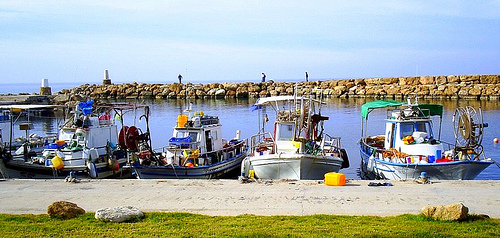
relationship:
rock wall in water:
[2, 75, 499, 103] [0, 83, 498, 180]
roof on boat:
[255, 96, 328, 107] [241, 95, 344, 179]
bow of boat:
[248, 155, 343, 179] [241, 95, 344, 179]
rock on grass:
[48, 201, 86, 220] [0, 214, 498, 237]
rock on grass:
[420, 203, 468, 222] [0, 214, 498, 237]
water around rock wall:
[0, 83, 498, 180] [2, 75, 499, 103]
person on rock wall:
[176, 73, 184, 84] [2, 75, 499, 103]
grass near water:
[0, 214, 498, 237] [0, 83, 498, 180]